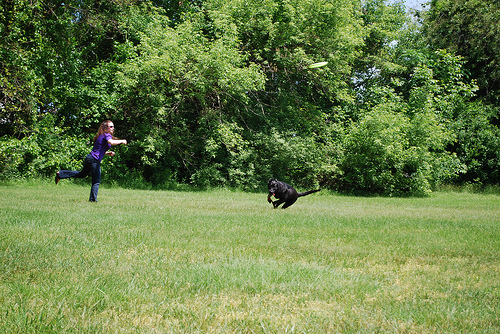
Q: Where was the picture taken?
A: A park.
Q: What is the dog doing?
A: Running.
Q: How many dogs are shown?
A: One.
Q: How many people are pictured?
A: One.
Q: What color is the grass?
A: Green.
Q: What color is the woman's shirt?
A: Purple.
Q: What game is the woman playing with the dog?
A: Fetch.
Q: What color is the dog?
A: Brown.